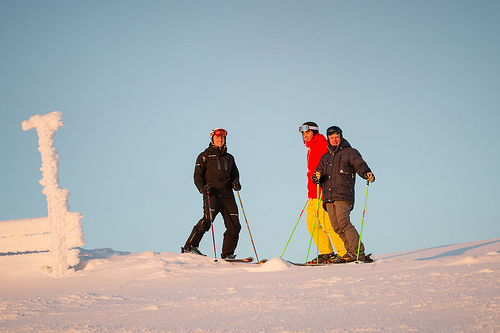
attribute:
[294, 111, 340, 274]
skier — posing, skiing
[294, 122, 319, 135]
goggles — white, black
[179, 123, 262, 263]
skier — posing, skiing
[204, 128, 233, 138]
goggles — red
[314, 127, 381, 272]
skier — posing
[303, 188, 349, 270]
pants — yellow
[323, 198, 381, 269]
pants — brown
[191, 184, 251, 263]
pants — black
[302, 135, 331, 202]
coat — red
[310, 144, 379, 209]
coat — black, grey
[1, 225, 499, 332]
snow — white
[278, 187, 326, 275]
poles — green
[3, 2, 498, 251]
sky — blue, clear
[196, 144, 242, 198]
jacket — black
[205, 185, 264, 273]
poles — red